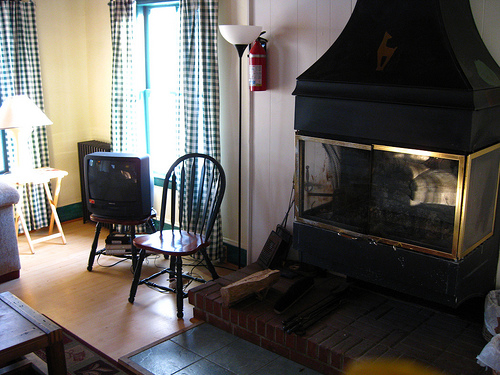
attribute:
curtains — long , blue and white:
[107, 0, 223, 261]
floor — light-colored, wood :
[0, 214, 246, 363]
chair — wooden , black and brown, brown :
[127, 151, 225, 320]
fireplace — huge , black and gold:
[291, 0, 497, 318]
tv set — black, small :
[82, 150, 154, 220]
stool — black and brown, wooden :
[86, 209, 170, 274]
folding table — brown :
[0, 167, 69, 255]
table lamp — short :
[0, 94, 55, 184]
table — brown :
[1, 290, 71, 373]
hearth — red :
[188, 230, 494, 370]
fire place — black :
[286, 5, 498, 321]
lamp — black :
[221, 26, 251, 267]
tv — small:
[83, 149, 155, 215]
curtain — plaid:
[105, 2, 138, 155]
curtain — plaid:
[175, 4, 231, 260]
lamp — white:
[0, 94, 51, 170]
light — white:
[220, 25, 258, 49]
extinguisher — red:
[250, 29, 271, 91]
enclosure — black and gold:
[288, 126, 499, 261]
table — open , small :
[0, 166, 68, 253]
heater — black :
[78, 139, 112, 224]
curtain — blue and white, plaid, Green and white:
[1, 2, 53, 234]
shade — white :
[222, 27, 257, 45]